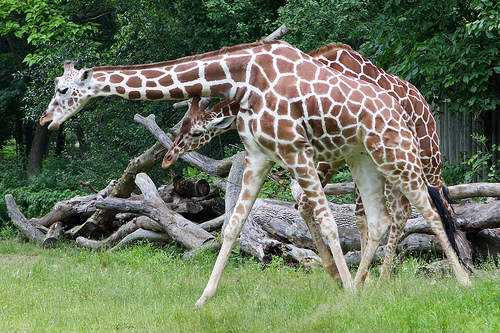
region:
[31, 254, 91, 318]
this is the grass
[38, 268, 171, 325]
the grass is green in color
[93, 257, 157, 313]
the grass is tall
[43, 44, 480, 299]
these are two giraffes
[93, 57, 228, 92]
the neck is long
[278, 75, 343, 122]
the fur is brown in color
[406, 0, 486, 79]
this is a tree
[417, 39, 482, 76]
the leaves are green in color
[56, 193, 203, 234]
these are several logs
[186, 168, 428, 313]
these are the giraffe's feet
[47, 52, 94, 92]
horns on top of the giraffes head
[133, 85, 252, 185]
giraffes head under the other giraffes neck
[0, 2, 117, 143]
tall green trees next to giraffes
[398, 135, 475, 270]
giraffe tail with black hair on the tip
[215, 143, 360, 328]
three giraffe legs showing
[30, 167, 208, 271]
tree stumps and branches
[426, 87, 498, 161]
a grey wooden fence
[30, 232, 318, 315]
green healthy grass to eat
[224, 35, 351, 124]
brown spots on the giraffes body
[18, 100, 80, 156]
the giraffes mouth is open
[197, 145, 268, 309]
long skinny leg of giraffe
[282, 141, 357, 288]
long skinny leg of giraffe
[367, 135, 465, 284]
long skinny leg of giraffe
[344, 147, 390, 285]
long skinny leg of giraffe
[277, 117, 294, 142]
brown spot of giraffe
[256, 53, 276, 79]
brown spot of giraffe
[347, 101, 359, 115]
brown spot of giraffe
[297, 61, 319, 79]
brown spot of giraffe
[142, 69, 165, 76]
brown spot of giraffe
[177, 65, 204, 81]
brown spot of giraffe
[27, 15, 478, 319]
a pair of giraffes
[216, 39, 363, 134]
brown and white fur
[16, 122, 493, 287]
a pile of logs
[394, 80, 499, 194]
a tall wooden fence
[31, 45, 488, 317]
some full grown wild animals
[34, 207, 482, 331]
some tall green grass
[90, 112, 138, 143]
some dense green leaves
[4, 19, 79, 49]
a few large leaves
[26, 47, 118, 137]
a giraffe with open mouth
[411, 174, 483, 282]
a long black tail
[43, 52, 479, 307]
Two giraffes in field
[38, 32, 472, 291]
Brown and white giraffes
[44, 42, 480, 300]
Giraffes with brown spots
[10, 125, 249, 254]
Tree logs on ground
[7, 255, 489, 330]
Light green grass on field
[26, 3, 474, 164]
Thick dark green bushes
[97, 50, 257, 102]
Long spotted giraffe neck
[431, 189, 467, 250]
Black tip of giraffe's tail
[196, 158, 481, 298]
Eight long giraffe legs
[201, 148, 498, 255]
Logs lying behind giraffes